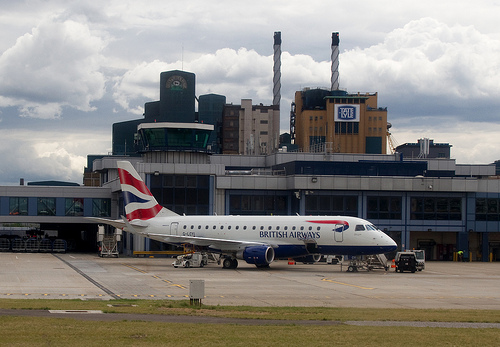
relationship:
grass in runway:
[10, 282, 492, 342] [25, 305, 483, 327]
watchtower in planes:
[132, 117, 223, 153] [115, 152, 402, 275]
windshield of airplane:
[344, 219, 374, 234] [86, 158, 398, 268]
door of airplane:
[332, 222, 346, 244] [86, 158, 398, 268]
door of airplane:
[332, 222, 342, 244] [87, 153, 413, 294]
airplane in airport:
[86, 158, 398, 268] [25, 30, 499, 245]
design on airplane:
[118, 167, 155, 225] [86, 158, 398, 268]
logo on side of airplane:
[255, 227, 321, 239] [86, 158, 398, 268]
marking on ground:
[117, 259, 230, 309] [2, 248, 497, 308]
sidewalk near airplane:
[0, 306, 496, 328] [86, 158, 398, 268]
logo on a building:
[333, 104, 361, 121] [292, 88, 390, 152]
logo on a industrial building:
[159, 63, 187, 106] [291, 88, 389, 154]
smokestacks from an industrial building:
[254, 10, 353, 147] [291, 88, 389, 151]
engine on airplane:
[247, 240, 282, 257] [94, 140, 442, 271]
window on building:
[61, 194, 86, 218] [8, 147, 498, 263]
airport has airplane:
[0, 38, 494, 267] [86, 158, 398, 268]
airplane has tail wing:
[86, 158, 398, 268] [104, 154, 181, 226]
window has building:
[361, 193, 406, 223] [0, 68, 498, 256]